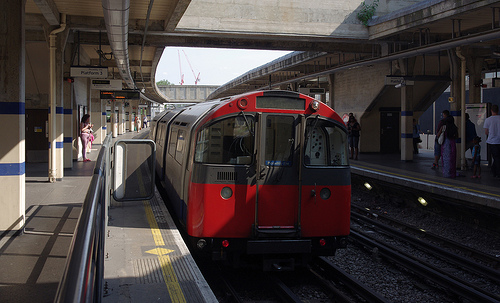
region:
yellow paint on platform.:
[145, 225, 175, 291]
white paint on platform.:
[185, 255, 218, 296]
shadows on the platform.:
[28, 201, 68, 292]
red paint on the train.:
[260, 195, 290, 217]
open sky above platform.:
[212, 56, 243, 74]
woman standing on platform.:
[77, 113, 99, 152]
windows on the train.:
[220, 136, 241, 151]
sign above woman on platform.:
[68, 66, 108, 76]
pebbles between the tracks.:
[365, 270, 392, 292]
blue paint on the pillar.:
[0, 99, 24, 123]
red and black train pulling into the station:
[158, 85, 368, 266]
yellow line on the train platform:
[138, 207, 185, 297]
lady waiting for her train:
[72, 107, 99, 167]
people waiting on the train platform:
[340, 103, 495, 178]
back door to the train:
[252, 107, 312, 246]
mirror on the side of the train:
[107, 137, 158, 206]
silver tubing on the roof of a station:
[101, 7, 143, 94]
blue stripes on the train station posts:
[393, 96, 416, 151]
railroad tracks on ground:
[366, 210, 449, 270]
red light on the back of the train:
[213, 239, 236, 254]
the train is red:
[128, 29, 370, 289]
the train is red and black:
[134, 74, 385, 293]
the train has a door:
[231, 92, 328, 252]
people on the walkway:
[394, 91, 496, 193]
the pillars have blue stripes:
[3, 46, 98, 213]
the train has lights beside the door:
[208, 170, 345, 212]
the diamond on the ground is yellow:
[136, 239, 185, 266]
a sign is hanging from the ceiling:
[64, 22, 126, 111]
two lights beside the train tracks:
[352, 164, 452, 283]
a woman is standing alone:
[56, 93, 120, 190]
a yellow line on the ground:
[123, 183, 206, 300]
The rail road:
[411, 208, 448, 288]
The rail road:
[397, 187, 445, 299]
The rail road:
[291, 259, 327, 299]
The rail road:
[331, 279, 356, 301]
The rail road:
[379, 223, 441, 300]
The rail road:
[373, 231, 411, 296]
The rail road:
[359, 247, 427, 301]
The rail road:
[403, 216, 465, 299]